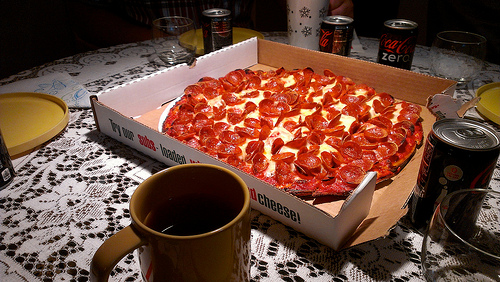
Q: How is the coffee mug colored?
A: In brown.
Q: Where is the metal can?
A: On table.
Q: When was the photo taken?
A: Meal time.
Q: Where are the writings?
A: On box.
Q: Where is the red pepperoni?
A: On pizza.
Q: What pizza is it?
A: Extra Pepperoni cheese pizza.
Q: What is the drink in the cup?
A: Black Coffee.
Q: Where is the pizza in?
A: To go Box.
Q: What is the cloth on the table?
A: Floral design cloth.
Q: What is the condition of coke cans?
A: Unopened.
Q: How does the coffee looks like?
A: Not hot.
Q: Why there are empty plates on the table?
A: To serve pizza.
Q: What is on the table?
A: Mug.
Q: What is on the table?
A: Pizza.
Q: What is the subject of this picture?
A: Pizza.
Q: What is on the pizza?
A: Pepperoni.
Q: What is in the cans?
A: Coke Zero.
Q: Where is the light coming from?
A: Above the table.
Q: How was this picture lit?
A: Indoor lighting.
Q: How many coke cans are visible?
A: Four.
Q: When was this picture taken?
A: Nighttime.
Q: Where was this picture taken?
A: At a table.